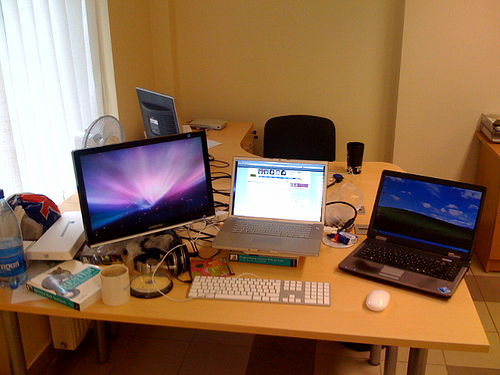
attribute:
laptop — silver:
[218, 154, 323, 262]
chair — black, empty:
[250, 99, 346, 183]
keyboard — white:
[183, 269, 342, 309]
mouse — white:
[364, 289, 392, 318]